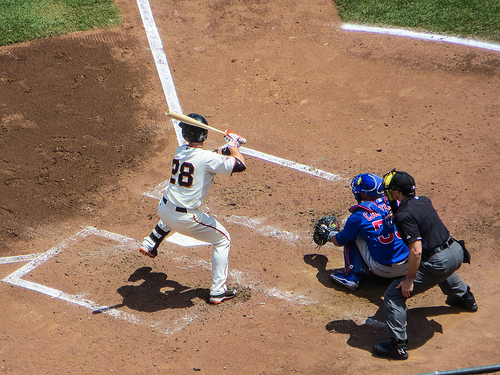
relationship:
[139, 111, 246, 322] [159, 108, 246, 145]
man holds bat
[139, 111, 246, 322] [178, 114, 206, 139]
man wears helmet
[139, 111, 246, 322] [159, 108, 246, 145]
man uses bat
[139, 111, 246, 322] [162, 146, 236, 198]
man wears jersey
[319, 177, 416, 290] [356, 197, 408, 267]
catcher wears jersey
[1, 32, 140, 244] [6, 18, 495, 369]
dirt on ground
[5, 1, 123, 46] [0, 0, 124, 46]
grass on grass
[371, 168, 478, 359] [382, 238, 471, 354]
umpire wears pants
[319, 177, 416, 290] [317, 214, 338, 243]
catcher has glove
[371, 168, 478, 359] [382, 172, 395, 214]
umpire has mask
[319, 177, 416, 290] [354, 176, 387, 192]
catcher wears helmet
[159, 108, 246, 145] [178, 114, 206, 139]
bat behind helmet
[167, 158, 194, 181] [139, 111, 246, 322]
number on man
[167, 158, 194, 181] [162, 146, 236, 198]
number on jersey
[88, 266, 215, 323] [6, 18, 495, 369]
shadow on ground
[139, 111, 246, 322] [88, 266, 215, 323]
man has shadow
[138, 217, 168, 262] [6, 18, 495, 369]
leg off ground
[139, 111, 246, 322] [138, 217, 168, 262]
man has leg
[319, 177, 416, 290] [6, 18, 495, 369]
catcher on ground